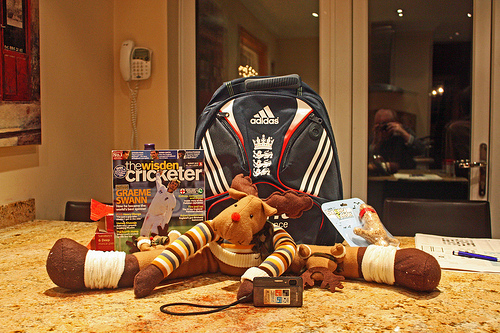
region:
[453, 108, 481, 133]
part of a window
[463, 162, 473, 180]
part of an handle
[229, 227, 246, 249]
part of a doll part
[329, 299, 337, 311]
part of a table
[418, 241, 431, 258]
part of a paper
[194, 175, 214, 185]
part of a book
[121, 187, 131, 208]
edge of a book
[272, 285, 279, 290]
part of a camera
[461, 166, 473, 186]
part of a handle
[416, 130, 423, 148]
part of a window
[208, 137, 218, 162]
edge of a bag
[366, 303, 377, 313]
part of a paper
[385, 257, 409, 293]
edge of a doll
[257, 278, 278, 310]
part of a camera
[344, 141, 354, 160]
edge of a door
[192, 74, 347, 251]
a backpack is on the floor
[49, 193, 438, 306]
a stuffed animal is on the floor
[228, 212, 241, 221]
the toy has a red nose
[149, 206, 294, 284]
the toy is wearing a shirt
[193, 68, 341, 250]
the backpack is black with graphic elements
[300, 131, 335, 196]
lines are on the backpack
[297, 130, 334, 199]
the lines are white in color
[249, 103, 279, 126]
a logo is on the back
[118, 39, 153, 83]
a phone is on the wall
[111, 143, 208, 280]
a magazine is on the floor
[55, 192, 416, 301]
a stuffed reindeer wearing a sweater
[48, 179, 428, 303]
a stuffed reindeer sitting on a counter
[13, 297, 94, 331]
tan granite surface of the counter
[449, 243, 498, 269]
a blue pen on a piece of paper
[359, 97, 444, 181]
reflection of the photographer in the window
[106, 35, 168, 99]
a white phone mounted on the wall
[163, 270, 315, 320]
a handheld camera on the counter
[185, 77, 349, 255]
a blue Adidas backpack with white and orange trim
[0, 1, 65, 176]
a piece of art on the wall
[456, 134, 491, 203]
shiny grey metal door handle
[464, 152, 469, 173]
part of an handle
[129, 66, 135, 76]
part of a phone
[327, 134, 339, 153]
edge of a bag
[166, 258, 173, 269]
part of an arm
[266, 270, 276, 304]
part of a camera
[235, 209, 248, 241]
part of a doll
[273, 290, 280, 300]
part of a camera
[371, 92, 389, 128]
part of a window